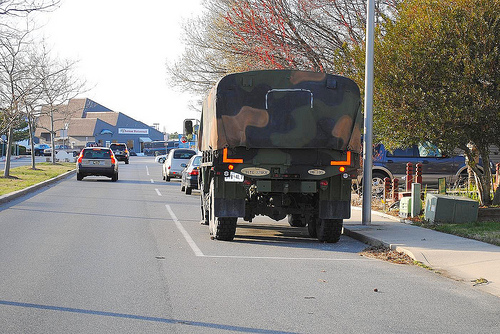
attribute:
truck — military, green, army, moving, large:
[179, 61, 363, 257]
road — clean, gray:
[140, 155, 215, 245]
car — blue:
[180, 155, 236, 205]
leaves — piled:
[350, 227, 432, 286]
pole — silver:
[353, 0, 386, 236]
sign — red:
[177, 131, 198, 149]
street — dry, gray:
[124, 168, 190, 256]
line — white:
[148, 178, 205, 253]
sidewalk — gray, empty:
[357, 203, 466, 257]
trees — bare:
[2, 36, 59, 172]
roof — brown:
[23, 94, 157, 152]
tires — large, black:
[191, 184, 349, 250]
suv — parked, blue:
[358, 129, 488, 210]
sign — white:
[111, 126, 153, 145]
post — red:
[166, 127, 204, 154]